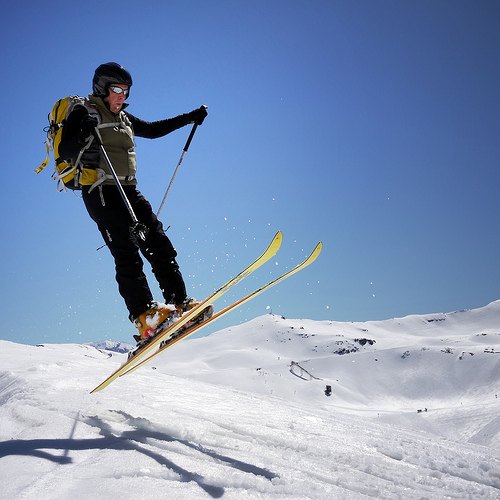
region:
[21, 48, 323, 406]
a guy that is skiing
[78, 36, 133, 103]
the head of a guy that is skiing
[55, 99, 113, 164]
the arm of a guy that is skiing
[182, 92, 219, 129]
the hand of a guy that is skiing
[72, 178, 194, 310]
the legs of a guy that is skiing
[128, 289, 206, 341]
the shoes of a guy that is skiing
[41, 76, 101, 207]
the backpack of a guy that is skiing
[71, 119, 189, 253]
the ski sticks of a guy that is skiing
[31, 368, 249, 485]
the shadow of a guy that is skiing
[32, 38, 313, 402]
skier doing tricks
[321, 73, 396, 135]
white clouds in blue sky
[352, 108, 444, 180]
white clouds in blue sky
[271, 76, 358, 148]
white clouds in blue sky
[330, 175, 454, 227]
white clouds in blue sky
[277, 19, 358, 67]
white clouds in blue sky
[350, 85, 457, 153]
white clouds in blue sky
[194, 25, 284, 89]
white clouds in blue sky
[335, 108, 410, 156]
white clouds in blue sky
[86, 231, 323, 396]
Two yellow skis on feet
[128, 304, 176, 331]
Orange ski boot on skier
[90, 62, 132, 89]
Black helmet on skier's head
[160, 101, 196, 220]
Ski pole in skier's hand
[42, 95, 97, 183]
Yellow and black backpack on skier's back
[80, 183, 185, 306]
Black pants on skier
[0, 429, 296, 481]
Shadow of skier in snow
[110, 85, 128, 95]
Ski goggles on man's face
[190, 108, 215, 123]
Black glove on skier's hand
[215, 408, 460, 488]
Trails of skis through white snow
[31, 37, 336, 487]
A man in the air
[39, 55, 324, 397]
A man skiing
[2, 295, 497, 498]
White snow covering the ground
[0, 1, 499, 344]
A clear blue sky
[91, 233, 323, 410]
A pair of yellow skis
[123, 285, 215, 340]
A yellow pair of ski boots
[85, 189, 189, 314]
A pair of black ski pants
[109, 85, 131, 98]
A pair of sunglasses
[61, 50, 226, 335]
A man holding ski poles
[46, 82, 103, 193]
A yellow and black backpack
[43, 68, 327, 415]
a man jumping on skis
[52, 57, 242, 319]
a man wearing a yellow backpack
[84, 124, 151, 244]
the ski pole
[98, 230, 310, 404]
the yellow skis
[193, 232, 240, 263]
snow flying up in the background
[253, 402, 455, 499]
tracks in the snow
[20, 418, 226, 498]
the shadow of the man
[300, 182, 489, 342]
the sky behind him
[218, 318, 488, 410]
a mountain behind the man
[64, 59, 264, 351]
a man with a helmet on